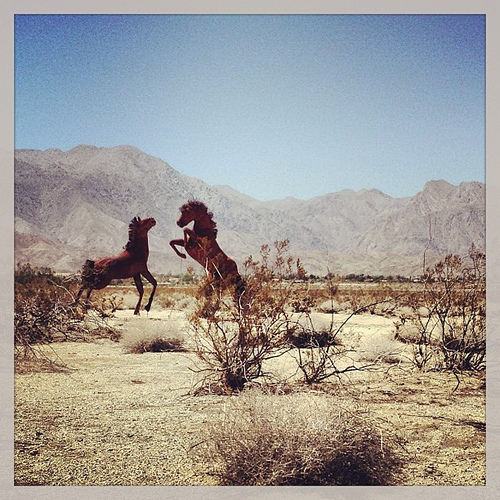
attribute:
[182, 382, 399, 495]
bush — small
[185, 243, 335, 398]
bush — medium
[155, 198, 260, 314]
horse — brown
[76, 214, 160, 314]
horses — brown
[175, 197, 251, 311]
horses — brown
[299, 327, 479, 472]
weeds — brown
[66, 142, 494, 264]
mountain range — highest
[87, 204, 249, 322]
horses — brown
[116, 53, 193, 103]
clouds — white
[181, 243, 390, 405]
bushes — dead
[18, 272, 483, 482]
ground — brown, parched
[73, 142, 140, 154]
peak — highest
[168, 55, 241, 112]
clouds — white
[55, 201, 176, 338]
horse — on all fours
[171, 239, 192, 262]
leg — bent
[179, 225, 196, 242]
leg — bent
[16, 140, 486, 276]
mountains — brown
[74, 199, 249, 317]
horses — playing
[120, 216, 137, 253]
hair — sticking up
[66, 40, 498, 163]
sjy — clear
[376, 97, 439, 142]
clouds — white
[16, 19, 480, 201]
sky — light blue, blue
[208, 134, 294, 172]
clouds — white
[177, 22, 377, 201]
sky — blue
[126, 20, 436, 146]
sky — blue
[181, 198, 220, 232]
hair — sticking up